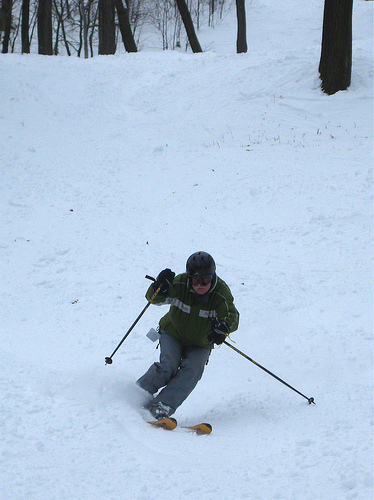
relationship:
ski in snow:
[181, 422, 213, 435] [53, 386, 305, 490]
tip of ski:
[203, 420, 213, 430] [143, 416, 178, 427]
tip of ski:
[169, 418, 177, 423] [182, 422, 212, 433]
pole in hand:
[104, 282, 163, 366] [207, 328, 227, 345]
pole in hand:
[223, 340, 317, 406] [154, 268, 175, 290]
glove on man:
[208, 317, 230, 343] [124, 250, 241, 419]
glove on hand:
[208, 317, 230, 343] [208, 320, 229, 345]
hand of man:
[208, 320, 229, 345] [124, 250, 241, 419]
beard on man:
[195, 286, 204, 290] [135, 251, 238, 419]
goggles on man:
[189, 275, 213, 287] [156, 254, 211, 421]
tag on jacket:
[144, 326, 163, 345] [145, 269, 239, 348]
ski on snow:
[181, 422, 213, 435] [36, 415, 167, 496]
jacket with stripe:
[142, 270, 244, 356] [161, 295, 218, 322]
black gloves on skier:
[148, 266, 181, 298] [134, 247, 241, 419]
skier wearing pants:
[134, 249, 240, 419] [132, 328, 213, 419]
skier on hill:
[134, 247, 241, 419] [0, 3, 372, 498]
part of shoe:
[150, 403, 169, 420] [121, 374, 225, 450]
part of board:
[188, 422, 205, 434] [181, 419, 213, 439]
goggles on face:
[190, 273, 212, 285] [192, 272, 214, 292]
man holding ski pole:
[157, 245, 222, 427] [104, 277, 166, 366]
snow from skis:
[94, 358, 166, 421] [121, 375, 201, 391]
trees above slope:
[4, 0, 363, 56] [43, 47, 323, 233]